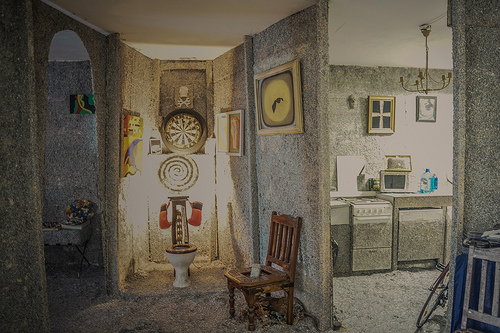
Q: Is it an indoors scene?
A: Yes, it is indoors.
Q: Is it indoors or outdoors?
A: It is indoors.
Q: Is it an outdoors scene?
A: No, it is indoors.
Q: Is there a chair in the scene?
A: Yes, there is a chair.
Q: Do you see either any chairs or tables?
A: Yes, there is a chair.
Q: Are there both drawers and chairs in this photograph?
A: No, there is a chair but no drawers.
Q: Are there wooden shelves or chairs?
A: Yes, there is a wood chair.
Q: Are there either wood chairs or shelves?
A: Yes, there is a wood chair.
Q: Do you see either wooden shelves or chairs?
A: Yes, there is a wood chair.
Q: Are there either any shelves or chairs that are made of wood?
A: Yes, the chair is made of wood.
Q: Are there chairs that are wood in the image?
A: Yes, there is a wood chair.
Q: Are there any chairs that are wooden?
A: Yes, there is a chair that is wooden.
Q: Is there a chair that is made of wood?
A: Yes, there is a chair that is made of wood.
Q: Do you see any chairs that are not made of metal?
A: Yes, there is a chair that is made of wood.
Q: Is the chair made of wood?
A: Yes, the chair is made of wood.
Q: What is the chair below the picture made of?
A: The chair is made of wood.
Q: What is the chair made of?
A: The chair is made of wood.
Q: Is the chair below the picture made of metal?
A: No, the chair is made of wood.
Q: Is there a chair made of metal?
A: No, there is a chair but it is made of wood.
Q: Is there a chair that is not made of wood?
A: No, there is a chair but it is made of wood.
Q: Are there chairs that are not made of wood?
A: No, there is a chair but it is made of wood.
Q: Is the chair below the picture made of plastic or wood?
A: The chair is made of wood.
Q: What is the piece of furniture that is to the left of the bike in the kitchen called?
A: The piece of furniture is a chair.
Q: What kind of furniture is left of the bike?
A: The piece of furniture is a chair.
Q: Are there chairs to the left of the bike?
A: Yes, there is a chair to the left of the bike.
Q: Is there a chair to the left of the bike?
A: Yes, there is a chair to the left of the bike.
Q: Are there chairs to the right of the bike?
A: No, the chair is to the left of the bike.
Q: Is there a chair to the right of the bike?
A: No, the chair is to the left of the bike.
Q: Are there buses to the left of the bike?
A: No, there is a chair to the left of the bike.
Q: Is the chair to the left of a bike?
A: Yes, the chair is to the left of a bike.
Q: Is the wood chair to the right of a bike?
A: No, the chair is to the left of a bike.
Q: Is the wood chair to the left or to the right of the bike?
A: The chair is to the left of the bike.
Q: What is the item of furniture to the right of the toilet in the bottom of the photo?
A: The piece of furniture is a chair.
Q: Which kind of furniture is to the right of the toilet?
A: The piece of furniture is a chair.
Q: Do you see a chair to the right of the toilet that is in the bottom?
A: Yes, there is a chair to the right of the toilet.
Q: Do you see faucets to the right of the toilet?
A: No, there is a chair to the right of the toilet.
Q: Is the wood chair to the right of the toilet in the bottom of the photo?
A: Yes, the chair is to the right of the toilet.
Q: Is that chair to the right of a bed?
A: No, the chair is to the right of the toilet.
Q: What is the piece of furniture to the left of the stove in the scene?
A: The piece of furniture is a chair.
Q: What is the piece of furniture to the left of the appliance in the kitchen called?
A: The piece of furniture is a chair.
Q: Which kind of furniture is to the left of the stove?
A: The piece of furniture is a chair.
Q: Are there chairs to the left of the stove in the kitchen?
A: Yes, there is a chair to the left of the stove.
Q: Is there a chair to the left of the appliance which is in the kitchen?
A: Yes, there is a chair to the left of the stove.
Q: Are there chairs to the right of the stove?
A: No, the chair is to the left of the stove.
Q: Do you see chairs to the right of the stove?
A: No, the chair is to the left of the stove.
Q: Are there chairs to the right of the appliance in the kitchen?
A: No, the chair is to the left of the stove.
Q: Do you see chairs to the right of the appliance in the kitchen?
A: No, the chair is to the left of the stove.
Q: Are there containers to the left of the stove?
A: No, there is a chair to the left of the stove.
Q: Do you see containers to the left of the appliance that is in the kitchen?
A: No, there is a chair to the left of the stove.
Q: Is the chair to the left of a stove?
A: Yes, the chair is to the left of a stove.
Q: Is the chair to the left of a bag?
A: No, the chair is to the left of a stove.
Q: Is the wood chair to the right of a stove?
A: No, the chair is to the left of a stove.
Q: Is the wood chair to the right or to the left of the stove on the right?
A: The chair is to the left of the stove.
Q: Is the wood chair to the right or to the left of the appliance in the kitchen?
A: The chair is to the left of the stove.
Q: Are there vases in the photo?
A: No, there are no vases.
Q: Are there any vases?
A: No, there are no vases.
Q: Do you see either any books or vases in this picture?
A: No, there are no vases or books.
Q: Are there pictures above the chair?
A: Yes, there is a picture above the chair.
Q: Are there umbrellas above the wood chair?
A: No, there is a picture above the chair.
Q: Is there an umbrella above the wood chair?
A: No, there is a picture above the chair.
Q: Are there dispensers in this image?
A: No, there are no dispensers.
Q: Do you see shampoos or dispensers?
A: No, there are no dispensers or shampoos.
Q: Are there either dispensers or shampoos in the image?
A: No, there are no dispensers or shampoos.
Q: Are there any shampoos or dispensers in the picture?
A: No, there are no dispensers or shampoos.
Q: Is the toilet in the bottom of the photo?
A: Yes, the toilet is in the bottom of the image.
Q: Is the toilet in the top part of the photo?
A: No, the toilet is in the bottom of the image.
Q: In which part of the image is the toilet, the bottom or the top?
A: The toilet is in the bottom of the image.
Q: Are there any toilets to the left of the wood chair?
A: Yes, there is a toilet to the left of the chair.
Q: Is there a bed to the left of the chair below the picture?
A: No, there is a toilet to the left of the chair.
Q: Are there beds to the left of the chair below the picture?
A: No, there is a toilet to the left of the chair.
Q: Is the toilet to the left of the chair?
A: Yes, the toilet is to the left of the chair.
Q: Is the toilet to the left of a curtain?
A: No, the toilet is to the left of the chair.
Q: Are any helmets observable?
A: No, there are no helmets.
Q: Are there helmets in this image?
A: No, there are no helmets.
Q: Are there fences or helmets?
A: No, there are no helmets or fences.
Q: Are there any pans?
A: No, there are no pans.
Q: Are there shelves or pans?
A: No, there are no pans or shelves.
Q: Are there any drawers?
A: No, there are no drawers.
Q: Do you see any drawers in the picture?
A: No, there are no drawers.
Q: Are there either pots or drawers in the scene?
A: No, there are no drawers or pots.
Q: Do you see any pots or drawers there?
A: No, there are no drawers or pots.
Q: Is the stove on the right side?
A: Yes, the stove is on the right of the image.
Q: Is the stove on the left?
A: No, the stove is on the right of the image.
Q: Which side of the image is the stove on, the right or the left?
A: The stove is on the right of the image.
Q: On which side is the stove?
A: The stove is on the right of the image.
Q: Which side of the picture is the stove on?
A: The stove is on the right of the image.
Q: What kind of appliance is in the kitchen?
A: The appliance is a stove.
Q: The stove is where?
A: The stove is in the kitchen.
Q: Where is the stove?
A: The stove is in the kitchen.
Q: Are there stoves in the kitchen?
A: Yes, there is a stove in the kitchen.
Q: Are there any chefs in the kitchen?
A: No, there is a stove in the kitchen.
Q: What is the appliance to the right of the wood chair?
A: The appliance is a stove.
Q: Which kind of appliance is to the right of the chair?
A: The appliance is a stove.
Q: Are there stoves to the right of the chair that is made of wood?
A: Yes, there is a stove to the right of the chair.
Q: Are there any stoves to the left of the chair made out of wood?
A: No, the stove is to the right of the chair.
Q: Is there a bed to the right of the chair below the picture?
A: No, there is a stove to the right of the chair.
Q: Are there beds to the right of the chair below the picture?
A: No, there is a stove to the right of the chair.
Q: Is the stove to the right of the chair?
A: Yes, the stove is to the right of the chair.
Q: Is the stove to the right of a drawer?
A: No, the stove is to the right of the chair.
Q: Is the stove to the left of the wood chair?
A: No, the stove is to the right of the chair.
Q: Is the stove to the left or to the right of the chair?
A: The stove is to the right of the chair.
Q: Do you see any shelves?
A: No, there are no shelves.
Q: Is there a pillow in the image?
A: No, there are no pillows.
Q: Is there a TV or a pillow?
A: No, there are no pillows or televisions.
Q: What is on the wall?
A: The picture is on the wall.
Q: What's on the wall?
A: The picture is on the wall.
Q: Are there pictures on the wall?
A: Yes, there is a picture on the wall.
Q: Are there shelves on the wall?
A: No, there is a picture on the wall.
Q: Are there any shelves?
A: No, there are no shelves.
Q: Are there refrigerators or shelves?
A: No, there are no shelves or refrigerators.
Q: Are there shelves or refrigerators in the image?
A: No, there are no shelves or refrigerators.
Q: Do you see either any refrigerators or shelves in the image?
A: No, there are no shelves or refrigerators.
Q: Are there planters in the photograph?
A: No, there are no planters.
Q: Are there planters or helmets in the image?
A: No, there are no planters or helmets.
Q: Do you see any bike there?
A: Yes, there is a bike.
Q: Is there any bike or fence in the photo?
A: Yes, there is a bike.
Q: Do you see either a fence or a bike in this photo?
A: Yes, there is a bike.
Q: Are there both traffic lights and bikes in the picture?
A: No, there is a bike but no traffic lights.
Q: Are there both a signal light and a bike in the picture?
A: No, there is a bike but no traffic lights.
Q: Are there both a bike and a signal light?
A: No, there is a bike but no traffic lights.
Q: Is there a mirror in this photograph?
A: No, there are no mirrors.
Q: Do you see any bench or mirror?
A: No, there are no mirrors or benches.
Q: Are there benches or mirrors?
A: No, there are no mirrors or benches.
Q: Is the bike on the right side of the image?
A: Yes, the bike is on the right of the image.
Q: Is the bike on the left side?
A: No, the bike is on the right of the image.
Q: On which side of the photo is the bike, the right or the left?
A: The bike is on the right of the image.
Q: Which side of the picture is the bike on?
A: The bike is on the right of the image.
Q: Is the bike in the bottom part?
A: Yes, the bike is in the bottom of the image.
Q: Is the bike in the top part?
A: No, the bike is in the bottom of the image.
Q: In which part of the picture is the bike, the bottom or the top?
A: The bike is in the bottom of the image.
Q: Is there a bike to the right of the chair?
A: Yes, there is a bike to the right of the chair.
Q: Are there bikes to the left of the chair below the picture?
A: No, the bike is to the right of the chair.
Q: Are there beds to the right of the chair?
A: No, there is a bike to the right of the chair.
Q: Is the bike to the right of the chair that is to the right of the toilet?
A: Yes, the bike is to the right of the chair.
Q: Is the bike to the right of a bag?
A: No, the bike is to the right of the chair.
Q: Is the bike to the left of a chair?
A: No, the bike is to the right of a chair.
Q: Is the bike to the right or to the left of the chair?
A: The bike is to the right of the chair.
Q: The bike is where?
A: The bike is in the kitchen.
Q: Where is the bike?
A: The bike is in the kitchen.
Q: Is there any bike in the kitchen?
A: Yes, there is a bike in the kitchen.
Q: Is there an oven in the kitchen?
A: No, there is a bike in the kitchen.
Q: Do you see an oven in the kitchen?
A: No, there is a bike in the kitchen.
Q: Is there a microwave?
A: Yes, there is a microwave.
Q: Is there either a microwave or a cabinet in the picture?
A: Yes, there is a microwave.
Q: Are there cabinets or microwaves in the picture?
A: Yes, there is a microwave.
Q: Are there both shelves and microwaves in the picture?
A: No, there is a microwave but no shelves.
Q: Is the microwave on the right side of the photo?
A: Yes, the microwave is on the right of the image.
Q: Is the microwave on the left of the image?
A: No, the microwave is on the right of the image.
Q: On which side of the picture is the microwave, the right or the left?
A: The microwave is on the right of the image.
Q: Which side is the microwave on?
A: The microwave is on the right of the image.